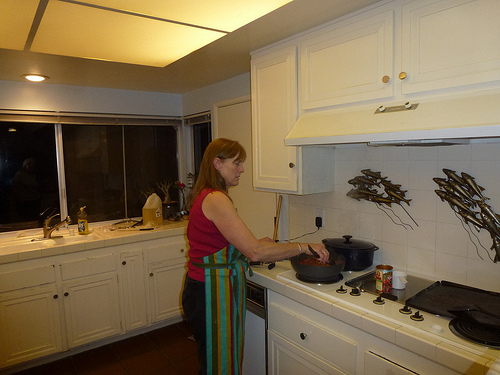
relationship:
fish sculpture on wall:
[432, 167, 500, 264] [178, 2, 498, 292]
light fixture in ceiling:
[0, 1, 291, 71] [1, 1, 295, 68]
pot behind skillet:
[319, 233, 380, 273] [286, 249, 345, 280]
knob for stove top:
[334, 283, 349, 296] [277, 260, 498, 357]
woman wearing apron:
[180, 136, 332, 374] [202, 239, 248, 374]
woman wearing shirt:
[180, 136, 332, 374] [187, 182, 229, 282]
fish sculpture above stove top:
[343, 166, 420, 234] [277, 260, 498, 357]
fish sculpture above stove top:
[432, 167, 500, 264] [277, 260, 498, 357]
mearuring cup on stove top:
[392, 267, 410, 291] [277, 260, 498, 357]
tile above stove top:
[286, 142, 500, 292] [277, 260, 498, 357]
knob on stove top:
[349, 286, 363, 298] [277, 260, 498, 357]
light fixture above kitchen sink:
[17, 67, 51, 85] [18, 229, 107, 248]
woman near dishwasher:
[180, 136, 332, 374] [240, 276, 269, 374]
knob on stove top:
[399, 303, 412, 315] [277, 260, 498, 357]